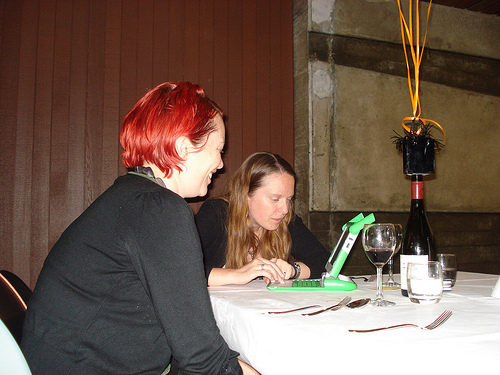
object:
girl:
[195, 152, 335, 288]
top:
[194, 198, 328, 283]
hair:
[224, 152, 298, 274]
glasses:
[361, 223, 396, 306]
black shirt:
[21, 165, 243, 374]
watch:
[294, 262, 301, 279]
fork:
[349, 309, 453, 333]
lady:
[20, 83, 260, 375]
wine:
[402, 175, 437, 290]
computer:
[267, 211, 376, 289]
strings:
[413, 0, 422, 117]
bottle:
[398, 174, 435, 292]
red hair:
[119, 81, 224, 179]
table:
[198, 265, 499, 373]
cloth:
[208, 271, 496, 373]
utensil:
[268, 304, 322, 314]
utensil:
[301, 295, 351, 316]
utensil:
[349, 275, 377, 282]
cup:
[407, 261, 443, 305]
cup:
[435, 253, 457, 291]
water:
[409, 278, 442, 295]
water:
[441, 266, 456, 287]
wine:
[365, 248, 393, 267]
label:
[400, 254, 428, 290]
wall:
[1, 1, 497, 287]